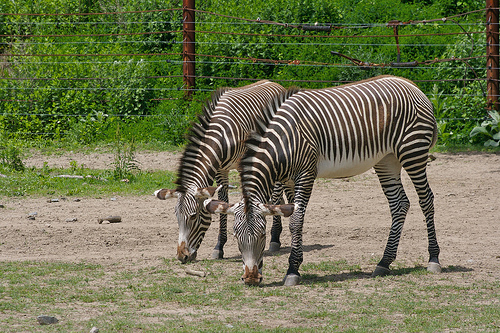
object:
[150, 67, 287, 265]
zebra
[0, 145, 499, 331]
field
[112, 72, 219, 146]
shrub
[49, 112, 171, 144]
shrub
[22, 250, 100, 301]
grass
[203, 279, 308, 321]
grass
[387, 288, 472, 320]
grass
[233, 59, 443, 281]
zebra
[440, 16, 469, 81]
shrub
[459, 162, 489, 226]
ground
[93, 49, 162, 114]
shrub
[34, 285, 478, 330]
field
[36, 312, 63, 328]
rock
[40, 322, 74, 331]
ground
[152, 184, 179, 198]
ear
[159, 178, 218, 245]
head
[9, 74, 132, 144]
shrub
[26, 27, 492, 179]
fence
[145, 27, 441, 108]
pole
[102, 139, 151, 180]
shrub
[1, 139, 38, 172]
shrub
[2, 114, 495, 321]
ground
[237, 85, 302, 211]
mane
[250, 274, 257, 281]
nose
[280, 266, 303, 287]
hoof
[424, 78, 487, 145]
shrub